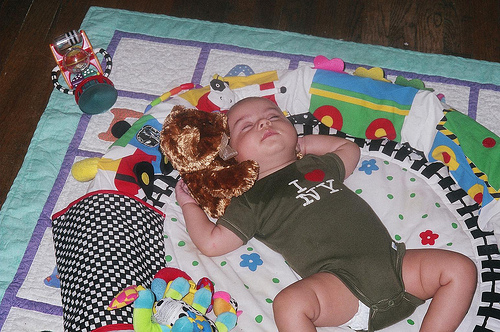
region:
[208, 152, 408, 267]
baby wearing a green tee shirt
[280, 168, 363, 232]
I love NY on a tee shirt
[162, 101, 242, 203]
Baby with a teddy bear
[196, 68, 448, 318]
baby sleeping on its back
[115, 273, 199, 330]
toy on the floor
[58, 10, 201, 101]
blanket laying on the floor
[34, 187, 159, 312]
checkered blanket on the floor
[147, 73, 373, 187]
baby on a bed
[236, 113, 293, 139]
baby with its eyes closed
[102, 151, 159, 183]
car on a blanket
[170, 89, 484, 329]
Baby on its back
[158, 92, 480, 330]
Baby is on its back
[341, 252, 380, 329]
Baby wearing a diaper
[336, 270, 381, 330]
Baby is wearing a diaper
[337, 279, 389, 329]
Baby wearing a white diaper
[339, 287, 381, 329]
Baby is wearing a white diaper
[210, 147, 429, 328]
Baby wearing a onesie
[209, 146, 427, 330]
Baby is wearing a onesie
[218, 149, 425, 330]
Baby wearing a green onesie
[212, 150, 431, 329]
Baby is wearing a green onesie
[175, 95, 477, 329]
the baby sleeping on the ground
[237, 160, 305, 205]
the wet spot on the baby's clothes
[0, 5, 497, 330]
the baby blanket on the ground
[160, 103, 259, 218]
the teddy bear near the baby's head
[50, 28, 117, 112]
the toy on the baby blanket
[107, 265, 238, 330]
the toy next to the baby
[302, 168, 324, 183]
the red heart on the baby's clothes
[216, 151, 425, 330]
the clothes on the baby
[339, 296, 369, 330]
the part of the baby's diaper showing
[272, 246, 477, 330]
the baby's chubby legs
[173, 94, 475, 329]
Very tired infant and teddy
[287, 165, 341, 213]
I LOVE NEW YORK logo on shirt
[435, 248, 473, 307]
Knee of sleeping infant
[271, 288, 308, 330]
Knee of sleeping infant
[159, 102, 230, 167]
Head of stuffed bear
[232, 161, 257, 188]
Paw of stuffed bear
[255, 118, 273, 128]
Nose of sleeping infant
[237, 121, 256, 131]
Eye of sleeping infant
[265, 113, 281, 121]
Eye of sleeping infant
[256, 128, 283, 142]
Mouth of sleeping infant